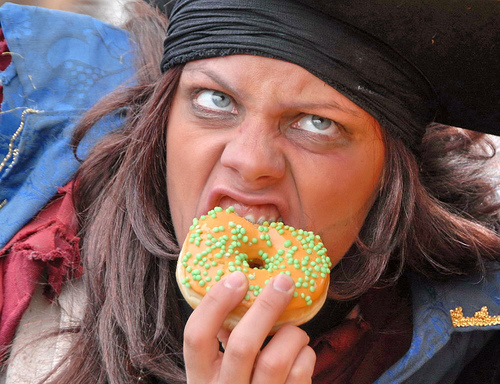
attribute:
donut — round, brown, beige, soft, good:
[181, 162, 340, 355]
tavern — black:
[154, 6, 466, 150]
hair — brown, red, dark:
[69, 81, 167, 259]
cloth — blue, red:
[4, 10, 89, 194]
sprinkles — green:
[201, 222, 259, 255]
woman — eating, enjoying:
[135, 23, 403, 353]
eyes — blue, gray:
[181, 81, 356, 156]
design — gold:
[439, 290, 494, 339]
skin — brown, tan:
[142, 53, 366, 192]